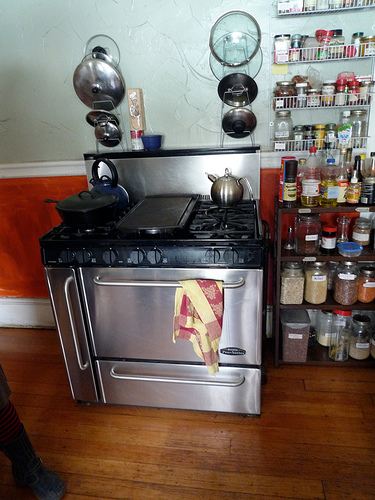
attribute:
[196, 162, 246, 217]
kettle — silver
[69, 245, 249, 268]
knobs — black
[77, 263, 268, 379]
oven door — silver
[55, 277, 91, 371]
handle — silver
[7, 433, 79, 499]
shoe — black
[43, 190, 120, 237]
pan — black